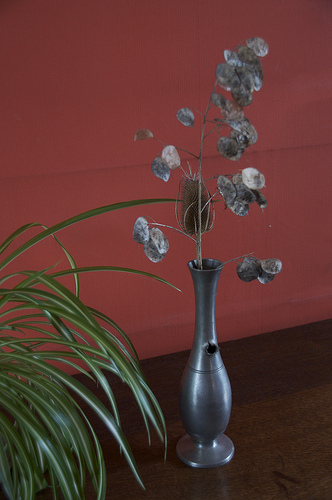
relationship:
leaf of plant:
[260, 257, 282, 273] [133, 35, 282, 469]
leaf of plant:
[161, 144, 182, 168] [133, 35, 282, 469]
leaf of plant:
[144, 226, 167, 262] [133, 35, 282, 469]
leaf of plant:
[176, 106, 194, 125] [133, 35, 282, 469]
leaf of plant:
[246, 36, 270, 57] [133, 35, 282, 469]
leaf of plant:
[230, 69, 252, 107] [133, 35, 282, 469]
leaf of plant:
[214, 63, 243, 90] [133, 35, 282, 469]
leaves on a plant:
[0, 392, 81, 500] [2, 193, 199, 497]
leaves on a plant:
[1, 383, 164, 465] [2, 193, 199, 497]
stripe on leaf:
[77, 390, 108, 423] [18, 350, 150, 492]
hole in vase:
[202, 340, 217, 355] [170, 252, 241, 474]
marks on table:
[271, 467, 301, 489] [224, 317, 330, 496]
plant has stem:
[130, 71, 276, 273] [195, 89, 216, 264]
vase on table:
[175, 247, 241, 471] [59, 318, 330, 497]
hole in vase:
[204, 341, 219, 357] [175, 257, 237, 465]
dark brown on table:
[270, 468, 298, 493] [59, 318, 330, 497]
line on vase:
[187, 359, 221, 376] [175, 257, 237, 465]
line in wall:
[2, 135, 328, 187] [0, 3, 330, 373]